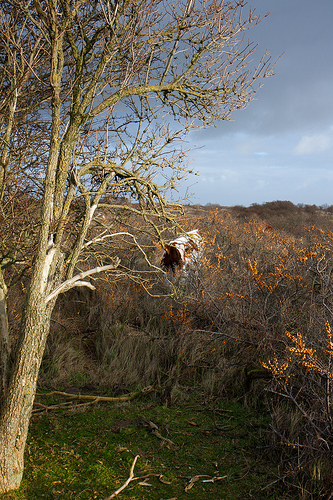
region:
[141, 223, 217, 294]
A cow in thick bushes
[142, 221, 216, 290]
A cow in thick bushes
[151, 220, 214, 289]
A cow in thick bushes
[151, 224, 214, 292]
A cow in thick bushes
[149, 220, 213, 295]
A cow in thick bushes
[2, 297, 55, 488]
the bark is green and brown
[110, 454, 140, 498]
a stick on the ground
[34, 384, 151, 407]
a broken branch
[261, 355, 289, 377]
the leaves are dead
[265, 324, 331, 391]
the leaves are orange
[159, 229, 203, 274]
the cow is white and brown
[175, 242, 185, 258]
white patch on the cow's face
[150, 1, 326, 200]
the skies are cloudy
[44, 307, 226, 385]
tall brown grass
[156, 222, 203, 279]
the cow is standing in the brush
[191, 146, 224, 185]
white clouds in blue sky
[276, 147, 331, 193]
white clouds in blue sky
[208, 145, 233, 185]
white clouds in blue sky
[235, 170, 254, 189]
white clouds in blue sky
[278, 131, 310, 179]
white clouds in blue sky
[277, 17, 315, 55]
white clouds in blue sky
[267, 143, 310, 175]
white clouds in blue sky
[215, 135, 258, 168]
white clouds in blue sky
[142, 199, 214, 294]
Cow walking in the forest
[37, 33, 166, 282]
tree with no leaves on it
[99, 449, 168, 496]
branch from the tree on the ground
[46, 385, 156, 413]
branch from the tree on the ground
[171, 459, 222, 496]
branch from the tree on the ground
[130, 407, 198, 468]
branch from the tree on the ground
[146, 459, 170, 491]
branch from the tree on the ground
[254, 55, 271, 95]
white clouds in blue sky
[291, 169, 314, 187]
white clouds in blue sky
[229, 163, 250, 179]
white clouds in blue sky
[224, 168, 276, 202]
white clouds in blue sky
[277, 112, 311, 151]
white clouds in blue sky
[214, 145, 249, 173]
white clouds in blue sky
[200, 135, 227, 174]
white clouds in blue sky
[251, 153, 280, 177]
white clouds in blue sky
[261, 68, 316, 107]
white clouds in blue sky